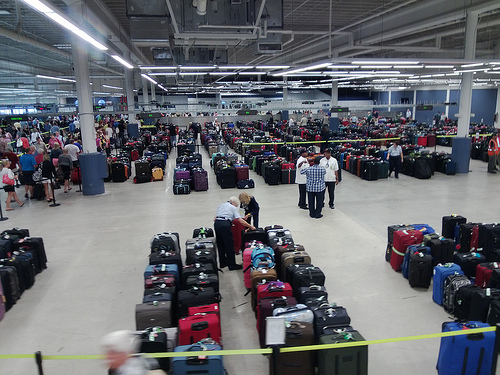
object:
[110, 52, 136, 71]
light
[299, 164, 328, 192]
shirt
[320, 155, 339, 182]
top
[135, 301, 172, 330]
suitcase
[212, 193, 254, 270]
person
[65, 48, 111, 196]
post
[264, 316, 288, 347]
sign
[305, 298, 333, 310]
briefcase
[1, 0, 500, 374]
airport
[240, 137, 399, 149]
strap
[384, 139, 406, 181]
woman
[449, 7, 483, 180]
pole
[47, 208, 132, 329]
floor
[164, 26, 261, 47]
pipe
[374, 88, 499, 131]
wall